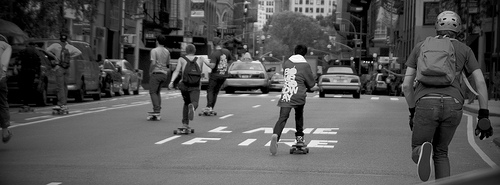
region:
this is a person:
[260, 26, 350, 166]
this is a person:
[200, 22, 257, 125]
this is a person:
[170, 30, 211, 135]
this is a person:
[132, 22, 193, 118]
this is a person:
[395, 8, 496, 173]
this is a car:
[308, 57, 373, 109]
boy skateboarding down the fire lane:
[265, 40, 316, 155]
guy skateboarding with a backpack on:
[400, 9, 495, 182]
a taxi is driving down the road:
[223, 51, 278, 96]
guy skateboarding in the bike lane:
[42, 30, 83, 115]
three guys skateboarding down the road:
[144, 33, 234, 137]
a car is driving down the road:
[317, 63, 362, 99]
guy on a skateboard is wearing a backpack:
[166, 43, 204, 136]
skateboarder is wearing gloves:
[401, 9, 496, 181]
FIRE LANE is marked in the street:
[179, 124, 341, 149]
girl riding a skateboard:
[167, 38, 217, 133]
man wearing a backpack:
[381, 13, 476, 163]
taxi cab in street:
[225, 44, 271, 91]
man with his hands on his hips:
[41, 28, 83, 113]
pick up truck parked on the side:
[40, 33, 105, 100]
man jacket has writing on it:
[264, 33, 323, 150]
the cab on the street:
[222, 48, 265, 91]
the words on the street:
[180, 121, 342, 153]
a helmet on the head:
[429, 6, 462, 32]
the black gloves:
[401, 104, 493, 144]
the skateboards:
[50, 101, 314, 155]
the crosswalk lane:
[158, 90, 456, 103]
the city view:
[1, 3, 498, 184]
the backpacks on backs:
[56, 32, 457, 84]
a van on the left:
[46, 34, 104, 102]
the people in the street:
[0, 6, 492, 183]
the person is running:
[389, 0, 491, 179]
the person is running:
[198, 32, 242, 117]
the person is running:
[175, 31, 223, 143]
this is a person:
[133, 31, 188, 148]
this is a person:
[42, 33, 99, 118]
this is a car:
[310, 62, 362, 106]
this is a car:
[220, 43, 289, 110]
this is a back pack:
[408, 25, 451, 89]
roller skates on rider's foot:
[279, 127, 322, 161]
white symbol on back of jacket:
[278, 60, 303, 105]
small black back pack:
[56, 47, 77, 73]